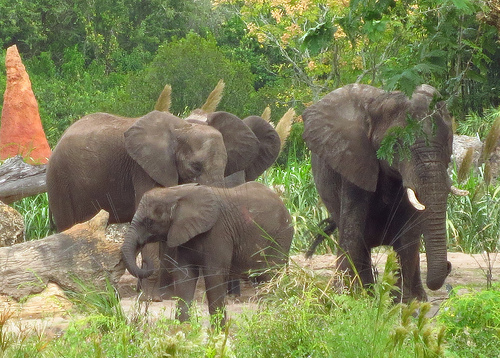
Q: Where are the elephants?
A: Grasss.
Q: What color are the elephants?
A: Grey.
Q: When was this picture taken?
A: Daytime.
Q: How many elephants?
A: 3.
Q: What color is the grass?
A: Green.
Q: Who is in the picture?
A: No one.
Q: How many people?
A: None.